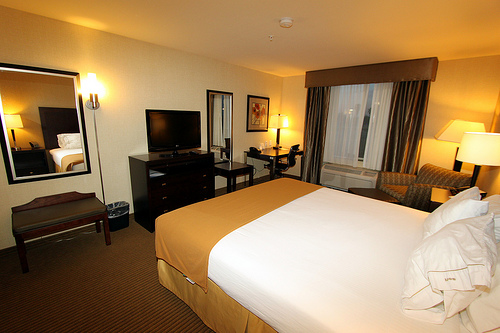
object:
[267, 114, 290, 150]
lamp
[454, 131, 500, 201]
lamp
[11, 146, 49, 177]
table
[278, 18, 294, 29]
smoke detector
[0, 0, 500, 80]
ceiling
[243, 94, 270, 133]
frame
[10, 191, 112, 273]
bench seat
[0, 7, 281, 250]
wall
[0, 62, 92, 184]
mirror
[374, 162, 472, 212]
chair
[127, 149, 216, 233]
dresser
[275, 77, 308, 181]
wall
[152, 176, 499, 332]
bed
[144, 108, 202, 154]
tv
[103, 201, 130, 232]
trash can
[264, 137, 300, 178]
chair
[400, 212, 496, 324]
pillow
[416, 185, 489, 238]
pillow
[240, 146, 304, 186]
desk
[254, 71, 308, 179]
corner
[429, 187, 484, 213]
table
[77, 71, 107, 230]
lamp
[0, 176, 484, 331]
floor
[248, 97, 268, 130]
print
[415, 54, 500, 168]
wall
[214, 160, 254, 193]
stool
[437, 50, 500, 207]
corner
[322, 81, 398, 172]
window